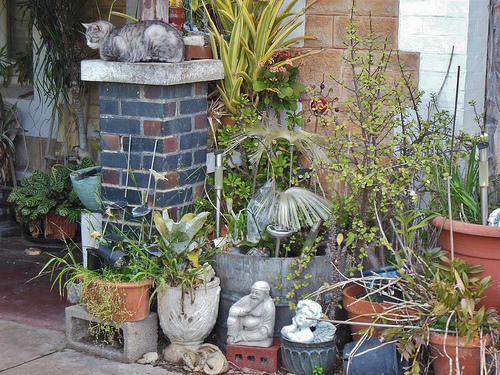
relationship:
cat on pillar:
[82, 13, 182, 73] [87, 66, 217, 240]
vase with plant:
[168, 293, 218, 362] [147, 210, 227, 287]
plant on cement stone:
[84, 273, 152, 332] [66, 313, 148, 363]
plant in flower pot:
[147, 210, 227, 287] [350, 337, 412, 370]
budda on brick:
[234, 289, 276, 344] [232, 347, 282, 370]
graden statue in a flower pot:
[234, 289, 276, 344] [350, 337, 412, 370]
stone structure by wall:
[240, 266, 294, 285] [309, 33, 356, 78]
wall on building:
[309, 33, 356, 78] [301, 5, 486, 147]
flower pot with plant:
[350, 337, 412, 370] [147, 210, 227, 287]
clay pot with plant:
[47, 205, 73, 249] [147, 210, 227, 287]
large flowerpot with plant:
[436, 214, 492, 317] [147, 210, 227, 287]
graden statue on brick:
[234, 289, 276, 344] [232, 347, 282, 370]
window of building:
[1, 12, 43, 101] [301, 5, 486, 147]